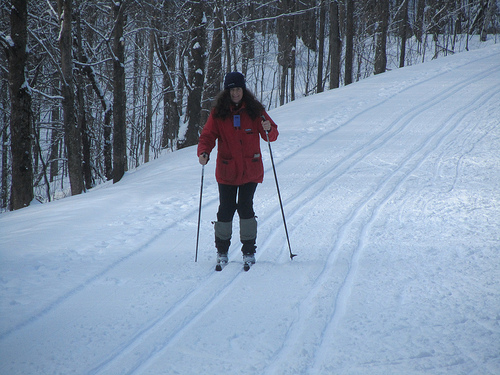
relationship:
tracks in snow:
[3, 7, 499, 374] [6, 42, 496, 375]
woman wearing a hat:
[197, 68, 278, 273] [224, 70, 249, 89]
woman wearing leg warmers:
[197, 68, 278, 273] [214, 183, 258, 252]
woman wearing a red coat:
[197, 68, 278, 273] [198, 91, 279, 185]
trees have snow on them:
[1, 2, 499, 212] [0, 2, 498, 213]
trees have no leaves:
[1, 2, 499, 212] [0, 0, 500, 216]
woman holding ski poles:
[197, 68, 278, 273] [192, 113, 298, 263]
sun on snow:
[2, 73, 499, 352] [6, 42, 496, 375]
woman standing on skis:
[197, 68, 278, 273] [192, 113, 298, 263]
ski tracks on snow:
[3, 7, 499, 374] [6, 42, 496, 375]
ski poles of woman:
[192, 113, 298, 263] [197, 68, 278, 273]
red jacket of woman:
[198, 91, 279, 185] [197, 68, 278, 273]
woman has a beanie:
[197, 68, 278, 273] [224, 70, 249, 89]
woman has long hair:
[197, 68, 278, 273] [212, 87, 267, 120]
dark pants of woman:
[214, 183, 258, 252] [197, 68, 278, 273]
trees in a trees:
[1, 2, 499, 212] [1, 2, 499, 212]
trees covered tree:
[1, 2, 499, 212] [1, 2, 499, 212]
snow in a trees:
[6, 42, 496, 375] [1, 2, 499, 212]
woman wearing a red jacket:
[197, 68, 278, 273] [198, 91, 279, 185]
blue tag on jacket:
[230, 111, 243, 129] [198, 91, 279, 185]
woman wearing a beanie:
[197, 68, 278, 273] [224, 70, 249, 89]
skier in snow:
[197, 68, 278, 273] [6, 42, 496, 375]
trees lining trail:
[1, 2, 499, 212] [3, 48, 498, 371]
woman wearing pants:
[197, 68, 278, 273] [214, 183, 258, 252]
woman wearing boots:
[197, 68, 278, 273] [212, 238, 260, 272]